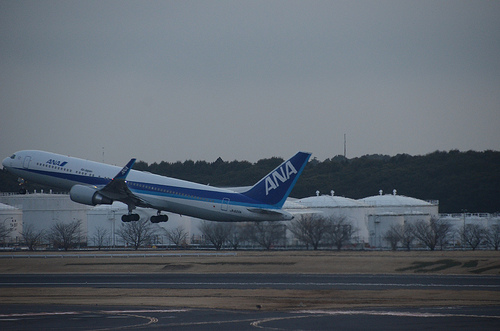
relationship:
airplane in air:
[0, 138, 334, 243] [1, 2, 498, 189]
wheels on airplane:
[118, 211, 172, 226] [1, 146, 316, 223]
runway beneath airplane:
[5, 266, 498, 330] [2, 146, 313, 233]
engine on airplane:
[69, 183, 113, 205] [1, 146, 316, 223]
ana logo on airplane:
[244, 148, 318, 195] [6, 138, 321, 233]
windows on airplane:
[37, 160, 73, 175] [2, 146, 313, 233]